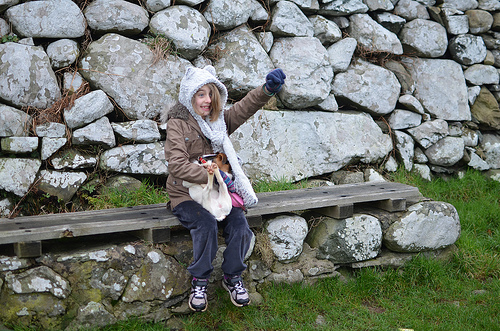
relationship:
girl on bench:
[159, 56, 251, 301] [12, 185, 416, 215]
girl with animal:
[159, 56, 251, 301] [180, 150, 237, 230]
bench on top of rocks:
[12, 185, 416, 215] [20, 207, 476, 255]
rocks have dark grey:
[87, 132, 168, 190] [135, 151, 159, 169]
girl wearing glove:
[159, 56, 251, 301] [267, 67, 293, 99]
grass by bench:
[275, 231, 492, 320] [12, 185, 416, 215]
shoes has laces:
[183, 273, 273, 314] [192, 282, 214, 309]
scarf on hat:
[177, 102, 254, 184] [180, 63, 236, 134]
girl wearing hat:
[159, 56, 251, 301] [180, 63, 236, 134]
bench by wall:
[12, 185, 416, 215] [17, 29, 426, 106]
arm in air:
[219, 52, 309, 166] [238, 40, 327, 71]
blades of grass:
[100, 179, 161, 205] [52, 190, 234, 215]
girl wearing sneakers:
[159, 56, 251, 301] [173, 263, 260, 304]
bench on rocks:
[12, 185, 416, 215] [20, 207, 476, 255]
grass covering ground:
[275, 231, 492, 320] [364, 264, 496, 295]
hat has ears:
[180, 63, 236, 134] [184, 66, 223, 74]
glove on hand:
[267, 67, 293, 99] [262, 80, 285, 89]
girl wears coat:
[159, 56, 251, 301] [161, 98, 244, 218]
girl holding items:
[159, 56, 251, 301] [180, 150, 237, 230]